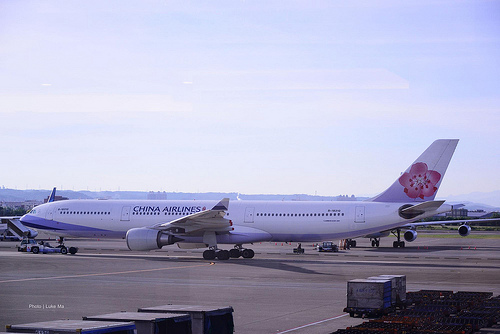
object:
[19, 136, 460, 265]
airplane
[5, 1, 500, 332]
airport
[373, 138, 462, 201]
tail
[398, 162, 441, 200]
flower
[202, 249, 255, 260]
wheels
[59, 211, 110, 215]
windows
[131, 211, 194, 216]
windows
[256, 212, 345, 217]
windows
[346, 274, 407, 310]
cargo boxes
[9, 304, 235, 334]
cargo boxes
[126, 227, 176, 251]
engine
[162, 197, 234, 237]
wing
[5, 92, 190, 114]
clouds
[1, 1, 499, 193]
sky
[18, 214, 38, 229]
nose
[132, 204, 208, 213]
logo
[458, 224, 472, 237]
engine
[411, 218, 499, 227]
wing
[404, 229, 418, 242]
engine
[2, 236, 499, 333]
ground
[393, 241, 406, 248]
wheels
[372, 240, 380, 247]
wheels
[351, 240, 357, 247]
wheels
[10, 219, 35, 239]
stairs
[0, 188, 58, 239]
airplane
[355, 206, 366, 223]
emergency door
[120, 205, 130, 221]
door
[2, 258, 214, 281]
line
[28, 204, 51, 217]
cockpit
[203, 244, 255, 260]
landing gear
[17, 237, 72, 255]
vehicle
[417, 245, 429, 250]
cones